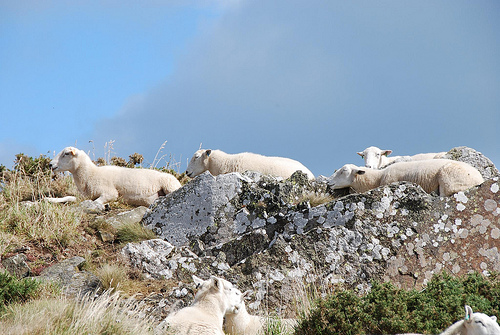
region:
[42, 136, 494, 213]
sheep on a hill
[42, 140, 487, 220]
four sheep on a hill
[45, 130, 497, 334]
sheep on a hillside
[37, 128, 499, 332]
sheep amongs the rocks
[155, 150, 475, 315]
a rocky hillside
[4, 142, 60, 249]
grass on a hillside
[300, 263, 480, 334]
a bush on a hillside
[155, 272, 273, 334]
two sheep in front of the rocks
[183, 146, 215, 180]
the head of a sheep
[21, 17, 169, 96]
blue sky in the distance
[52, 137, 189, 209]
sheep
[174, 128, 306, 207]
sheep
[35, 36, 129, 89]
white clouds in blue sky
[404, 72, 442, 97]
white clouds in blue sky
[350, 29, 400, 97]
white clouds in blue sky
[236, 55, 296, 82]
white clouds in blue sky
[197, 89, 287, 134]
white clouds in blue sky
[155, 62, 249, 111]
white clouds in blue sky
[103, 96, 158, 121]
white clouds in blue sky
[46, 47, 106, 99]
white clouds in blue sky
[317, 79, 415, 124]
white clouds in blue sky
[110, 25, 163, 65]
white clouds in blue sky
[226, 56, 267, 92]
white clouds in blue sky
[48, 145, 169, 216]
white sheep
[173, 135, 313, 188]
white sheep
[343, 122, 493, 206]
white sheep on hill top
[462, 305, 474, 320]
sheep has an ear tag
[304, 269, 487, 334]
juniper bush grows by rocks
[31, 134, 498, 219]
four sheep sit on top of the hill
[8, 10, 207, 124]
a patch of clear blue sky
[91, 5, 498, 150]
a cloud or smoke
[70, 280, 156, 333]
grass is ripening seeds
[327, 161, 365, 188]
sheep eye is closed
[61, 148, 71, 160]
sheep eye is open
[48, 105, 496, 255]
several sheep on a rocky hill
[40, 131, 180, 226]
a sheep lying down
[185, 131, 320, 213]
a sheep lying down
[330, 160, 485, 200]
a sheep lying down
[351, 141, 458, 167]
a sheep lying down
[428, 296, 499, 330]
head of a sheep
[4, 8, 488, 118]
a clear blue sky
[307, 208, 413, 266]
lichen on a boulder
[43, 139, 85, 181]
the head of a sheep